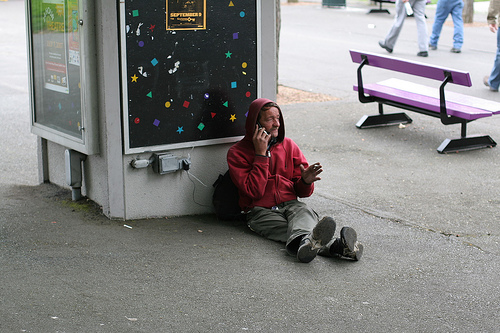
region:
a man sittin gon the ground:
[219, 97, 364, 299]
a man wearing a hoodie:
[208, 58, 328, 239]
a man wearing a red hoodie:
[246, 65, 299, 233]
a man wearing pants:
[229, 115, 405, 319]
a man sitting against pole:
[172, 63, 329, 286]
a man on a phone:
[234, 86, 393, 306]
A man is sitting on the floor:
[227, 80, 384, 277]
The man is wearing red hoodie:
[218, 90, 330, 198]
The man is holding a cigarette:
[291, 145, 349, 206]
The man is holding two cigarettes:
[244, 127, 341, 191]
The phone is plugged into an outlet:
[154, 142, 206, 199]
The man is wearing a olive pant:
[232, 200, 329, 246]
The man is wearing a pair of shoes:
[275, 216, 373, 271]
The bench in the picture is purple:
[324, 41, 490, 156]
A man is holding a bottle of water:
[381, 1, 438, 60]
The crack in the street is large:
[324, 185, 492, 260]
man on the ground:
[198, 83, 379, 253]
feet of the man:
[296, 205, 366, 255]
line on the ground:
[375, 190, 450, 245]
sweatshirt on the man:
[225, 70, 320, 180]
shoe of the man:
[281, 210, 336, 265]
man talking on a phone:
[201, 85, 356, 207]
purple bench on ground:
[310, 51, 487, 132]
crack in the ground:
[375, 182, 480, 257]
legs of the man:
[365, 12, 437, 48]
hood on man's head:
[233, 84, 300, 152]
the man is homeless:
[48, 71, 480, 331]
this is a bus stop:
[312, 35, 496, 189]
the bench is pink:
[357, 41, 497, 141]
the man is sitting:
[211, 83, 409, 315]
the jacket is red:
[245, 148, 349, 209]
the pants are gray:
[254, 191, 361, 263]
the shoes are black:
[284, 207, 376, 288]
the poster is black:
[115, 17, 272, 139]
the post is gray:
[52, 85, 257, 255]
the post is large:
[32, 28, 222, 205]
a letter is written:
[173, 12, 175, 14]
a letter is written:
[176, 10, 182, 22]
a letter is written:
[183, 13, 187, 18]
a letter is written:
[198, 10, 210, 27]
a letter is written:
[191, 14, 193, 20]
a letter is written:
[185, 10, 196, 24]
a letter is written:
[179, 10, 186, 19]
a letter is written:
[182, 15, 189, 23]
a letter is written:
[180, 14, 183, 17]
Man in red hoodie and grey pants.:
[226, 96, 365, 262]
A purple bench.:
[347, 48, 499, 155]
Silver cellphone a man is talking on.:
[254, 123, 269, 140]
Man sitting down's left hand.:
[301, 160, 323, 185]